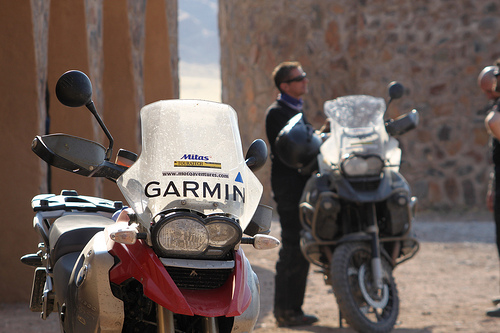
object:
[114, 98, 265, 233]
plastic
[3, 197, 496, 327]
ground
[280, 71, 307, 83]
sun glasses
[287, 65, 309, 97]
face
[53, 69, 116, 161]
side mirror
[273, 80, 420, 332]
bike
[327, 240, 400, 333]
tire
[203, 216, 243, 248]
head light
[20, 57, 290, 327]
bike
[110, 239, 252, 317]
fender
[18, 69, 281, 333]
motorcycle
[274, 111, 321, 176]
helmet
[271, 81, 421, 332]
motorcycle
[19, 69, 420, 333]
motorbikes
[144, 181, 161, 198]
letter g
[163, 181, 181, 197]
letter a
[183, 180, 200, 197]
letter r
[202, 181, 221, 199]
letter m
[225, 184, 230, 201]
letter i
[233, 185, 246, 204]
letter n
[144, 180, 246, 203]
word "garmin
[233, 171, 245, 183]
blue triangle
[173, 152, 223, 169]
"mitas" logo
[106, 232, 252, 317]
red motorcycle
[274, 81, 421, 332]
black motorcycle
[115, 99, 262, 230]
white wind shield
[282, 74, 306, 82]
glasses on face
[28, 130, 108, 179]
side mirror on bike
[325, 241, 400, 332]
black tire on bike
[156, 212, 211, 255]
light on bike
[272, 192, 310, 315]
denim jeans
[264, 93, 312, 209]
black jacket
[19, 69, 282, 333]
is unattended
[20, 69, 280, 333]
motorcycle is vacan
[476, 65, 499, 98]
helmet is hanging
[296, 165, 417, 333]
motorcycle is black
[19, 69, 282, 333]
its kickstand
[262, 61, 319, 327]
man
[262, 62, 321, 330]
man is standing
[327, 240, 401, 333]
front of two parked